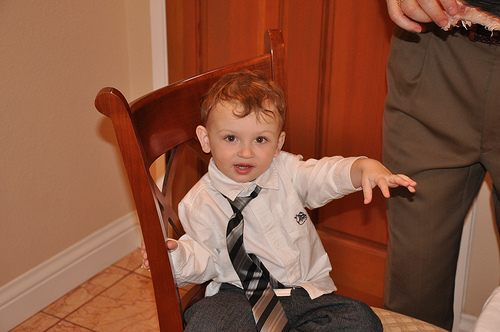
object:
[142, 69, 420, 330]
boy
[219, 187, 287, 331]
tie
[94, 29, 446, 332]
chair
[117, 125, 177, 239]
wood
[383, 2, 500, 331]
man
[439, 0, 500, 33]
food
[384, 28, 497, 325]
pants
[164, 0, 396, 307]
door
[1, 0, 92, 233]
wall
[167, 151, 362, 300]
shirt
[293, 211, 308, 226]
logo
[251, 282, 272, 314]
stripes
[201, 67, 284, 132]
hair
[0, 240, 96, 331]
tile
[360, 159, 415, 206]
hand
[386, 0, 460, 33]
hand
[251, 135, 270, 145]
eyes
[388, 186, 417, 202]
shadow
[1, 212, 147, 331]
baseboard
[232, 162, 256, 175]
mouth